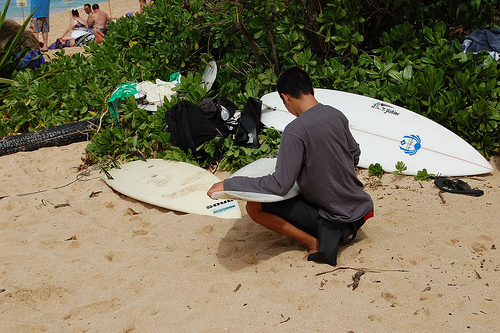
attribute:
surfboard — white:
[100, 157, 244, 219]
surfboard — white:
[260, 89, 497, 179]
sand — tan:
[85, 215, 205, 332]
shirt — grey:
[223, 105, 374, 221]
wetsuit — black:
[197, 92, 263, 150]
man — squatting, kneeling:
[208, 68, 373, 263]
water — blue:
[3, 1, 28, 18]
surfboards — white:
[103, 86, 494, 221]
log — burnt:
[1, 118, 105, 159]